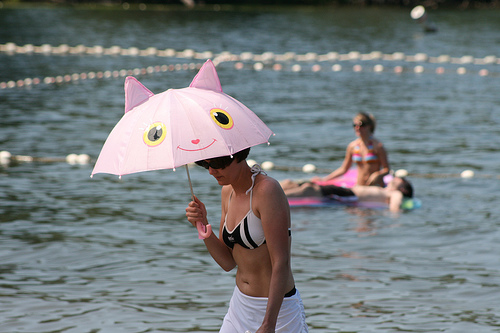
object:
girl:
[345, 101, 405, 238]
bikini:
[348, 140, 379, 167]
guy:
[287, 174, 414, 207]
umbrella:
[80, 58, 276, 179]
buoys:
[430, 65, 448, 77]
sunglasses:
[192, 159, 247, 170]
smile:
[178, 141, 228, 166]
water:
[245, 23, 379, 36]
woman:
[183, 147, 302, 331]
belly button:
[236, 277, 256, 289]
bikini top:
[220, 166, 293, 251]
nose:
[180, 129, 206, 149]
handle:
[193, 220, 217, 239]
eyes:
[207, 107, 239, 131]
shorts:
[218, 293, 311, 325]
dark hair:
[235, 153, 249, 158]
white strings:
[248, 164, 262, 222]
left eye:
[123, 114, 185, 149]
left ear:
[111, 74, 161, 115]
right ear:
[183, 63, 239, 96]